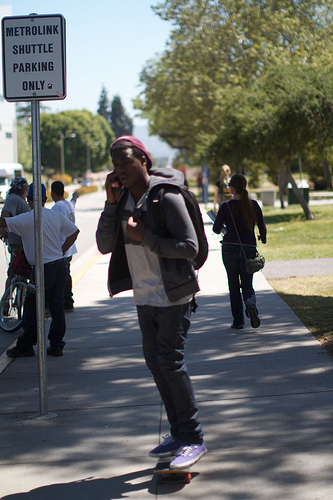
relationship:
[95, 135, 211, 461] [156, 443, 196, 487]
man man on skateboard skateboard has a man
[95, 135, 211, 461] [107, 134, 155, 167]
man cap red cap is on man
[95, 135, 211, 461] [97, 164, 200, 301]
man jacket gray jacket is on man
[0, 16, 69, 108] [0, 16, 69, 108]
sign sidewalk has a sign sign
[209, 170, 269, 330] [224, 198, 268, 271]
girl purse on shoulder shoulder carries pur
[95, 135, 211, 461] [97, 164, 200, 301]
man jacket gray jacket is hooded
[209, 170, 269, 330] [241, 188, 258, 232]
girl ponytail long ponytail is on girl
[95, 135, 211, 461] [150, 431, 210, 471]
man shoes are blue tennis shoes on boy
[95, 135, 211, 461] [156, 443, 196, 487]
man man in street skateboard is in str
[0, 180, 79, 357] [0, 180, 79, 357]
guy man in street guy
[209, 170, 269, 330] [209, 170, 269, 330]
girl woman on street girl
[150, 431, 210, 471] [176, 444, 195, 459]
shoes are purple shoes have laces laces are on shoes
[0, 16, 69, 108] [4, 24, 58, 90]
sign sign with lettering lettering is black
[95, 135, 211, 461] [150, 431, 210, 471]
man person on a skateboa shoes are blue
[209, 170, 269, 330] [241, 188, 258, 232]
girl hair in ponytail woman has ponytail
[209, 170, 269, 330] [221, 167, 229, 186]
girl hair in ponytail woman has ponytail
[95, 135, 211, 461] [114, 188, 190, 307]
man man wearing teeshirt teeshirt is white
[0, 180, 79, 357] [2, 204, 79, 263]
guy man wearing teeshirt t-shirt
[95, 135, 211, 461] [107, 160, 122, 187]
man talking on cell phone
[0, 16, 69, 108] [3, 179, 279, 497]
sign on sidewalk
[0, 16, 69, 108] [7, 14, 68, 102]
sign with border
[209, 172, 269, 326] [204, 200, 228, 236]
girl carrying books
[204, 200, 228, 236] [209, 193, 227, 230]
books on arm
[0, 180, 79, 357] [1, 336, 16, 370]
guy standing on curb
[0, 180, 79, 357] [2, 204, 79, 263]
guy wearing t-shirt